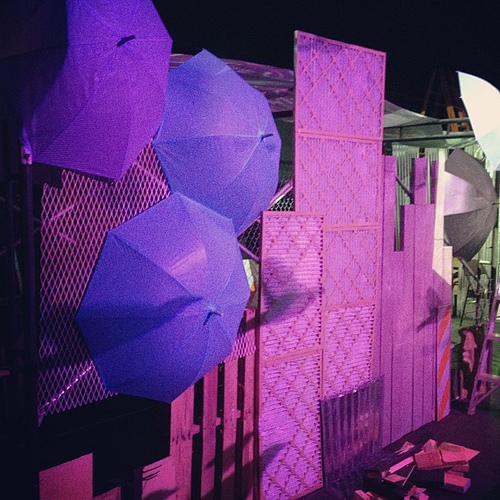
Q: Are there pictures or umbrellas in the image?
A: Yes, there is an umbrella.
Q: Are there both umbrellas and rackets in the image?
A: No, there is an umbrella but no rackets.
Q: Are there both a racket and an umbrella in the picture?
A: No, there is an umbrella but no rackets.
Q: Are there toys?
A: No, there are no toys.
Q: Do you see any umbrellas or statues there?
A: Yes, there is an umbrella.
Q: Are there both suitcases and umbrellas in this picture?
A: No, there is an umbrella but no suitcases.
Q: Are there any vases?
A: No, there are no vases.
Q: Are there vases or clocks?
A: No, there are no vases or clocks.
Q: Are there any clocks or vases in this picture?
A: No, there are no vases or clocks.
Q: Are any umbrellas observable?
A: Yes, there is an umbrella.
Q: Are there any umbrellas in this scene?
A: Yes, there is an umbrella.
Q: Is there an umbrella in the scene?
A: Yes, there is an umbrella.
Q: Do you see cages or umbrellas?
A: Yes, there is an umbrella.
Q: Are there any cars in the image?
A: No, there are no cars.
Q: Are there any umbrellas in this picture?
A: Yes, there is an umbrella.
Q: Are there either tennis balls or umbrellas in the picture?
A: Yes, there is an umbrella.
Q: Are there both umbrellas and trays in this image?
A: No, there is an umbrella but no trays.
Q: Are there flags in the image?
A: No, there are no flags.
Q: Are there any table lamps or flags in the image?
A: No, there are no flags or table lamps.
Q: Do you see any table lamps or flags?
A: No, there are no flags or table lamps.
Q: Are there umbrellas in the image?
A: Yes, there is an umbrella.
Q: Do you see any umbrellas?
A: Yes, there is an umbrella.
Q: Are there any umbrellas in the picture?
A: Yes, there is an umbrella.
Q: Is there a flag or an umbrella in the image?
A: Yes, there is an umbrella.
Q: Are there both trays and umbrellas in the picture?
A: No, there is an umbrella but no trays.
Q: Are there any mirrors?
A: No, there are no mirrors.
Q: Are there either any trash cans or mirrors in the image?
A: No, there are no mirrors or trash cans.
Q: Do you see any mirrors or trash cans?
A: No, there are no mirrors or trash cans.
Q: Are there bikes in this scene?
A: No, there are no bikes.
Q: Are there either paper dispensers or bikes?
A: No, there are no bikes or paper dispensers.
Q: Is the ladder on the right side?
A: Yes, the ladder is on the right of the image.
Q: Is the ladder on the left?
A: No, the ladder is on the right of the image.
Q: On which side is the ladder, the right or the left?
A: The ladder is on the right of the image.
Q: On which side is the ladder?
A: The ladder is on the right of the image.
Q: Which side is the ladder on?
A: The ladder is on the right of the image.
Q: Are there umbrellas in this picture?
A: Yes, there is an umbrella.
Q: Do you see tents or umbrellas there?
A: Yes, there is an umbrella.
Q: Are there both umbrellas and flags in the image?
A: No, there is an umbrella but no flags.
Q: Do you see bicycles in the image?
A: No, there are no bicycles.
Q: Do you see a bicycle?
A: No, there are no bicycles.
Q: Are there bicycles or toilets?
A: No, there are no bicycles or toilets.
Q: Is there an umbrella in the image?
A: Yes, there is an umbrella.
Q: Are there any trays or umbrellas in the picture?
A: Yes, there is an umbrella.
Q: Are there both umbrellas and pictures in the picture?
A: No, there is an umbrella but no pictures.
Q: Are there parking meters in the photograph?
A: No, there are no parking meters.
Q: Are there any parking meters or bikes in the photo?
A: No, there are no parking meters or bikes.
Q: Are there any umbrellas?
A: Yes, there are umbrellas.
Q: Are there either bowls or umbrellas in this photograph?
A: Yes, there are umbrellas.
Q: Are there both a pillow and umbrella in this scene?
A: No, there are umbrellas but no pillows.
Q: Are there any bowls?
A: No, there are no bowls.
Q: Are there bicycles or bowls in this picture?
A: No, there are no bowls or bicycles.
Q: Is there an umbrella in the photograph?
A: Yes, there is an umbrella.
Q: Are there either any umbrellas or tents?
A: Yes, there is an umbrella.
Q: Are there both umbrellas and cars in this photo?
A: No, there is an umbrella but no cars.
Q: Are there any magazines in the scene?
A: No, there are no magazines.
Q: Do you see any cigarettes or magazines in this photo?
A: No, there are no magazines or cigarettes.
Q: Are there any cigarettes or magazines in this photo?
A: No, there are no magazines or cigarettes.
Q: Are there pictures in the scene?
A: No, there are no pictures.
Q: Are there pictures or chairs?
A: No, there are no pictures or chairs.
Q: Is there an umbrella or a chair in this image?
A: Yes, there are umbrellas.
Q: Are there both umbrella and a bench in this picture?
A: No, there are umbrellas but no benches.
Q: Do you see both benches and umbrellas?
A: No, there are umbrellas but no benches.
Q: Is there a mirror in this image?
A: No, there are no mirrors.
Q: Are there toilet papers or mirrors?
A: No, there are no mirrors or toilet papers.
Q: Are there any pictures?
A: No, there are no pictures.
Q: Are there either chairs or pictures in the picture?
A: No, there are no pictures or chairs.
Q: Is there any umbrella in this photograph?
A: Yes, there is an umbrella.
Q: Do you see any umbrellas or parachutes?
A: Yes, there is an umbrella.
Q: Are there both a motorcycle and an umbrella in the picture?
A: No, there is an umbrella but no motorcycles.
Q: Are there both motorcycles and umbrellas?
A: No, there is an umbrella but no motorcycles.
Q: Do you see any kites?
A: No, there are no kites.